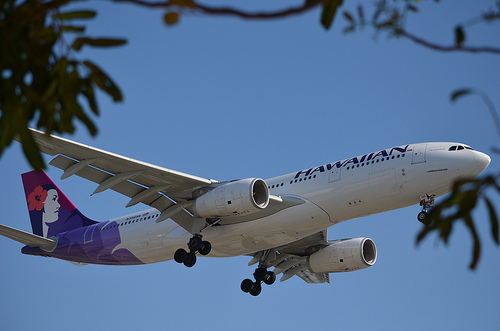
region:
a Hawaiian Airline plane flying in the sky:
[1, 116, 492, 298]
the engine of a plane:
[185, 177, 271, 219]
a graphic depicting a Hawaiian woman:
[15, 166, 142, 272]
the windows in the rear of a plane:
[106, 212, 158, 227]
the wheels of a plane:
[171, 232, 275, 298]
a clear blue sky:
[128, 49, 444, 143]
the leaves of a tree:
[6, 6, 118, 118]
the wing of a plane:
[31, 129, 196, 206]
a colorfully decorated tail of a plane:
[16, 168, 92, 228]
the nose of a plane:
[466, 147, 491, 168]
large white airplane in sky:
[25, 81, 482, 298]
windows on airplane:
[266, 168, 324, 195]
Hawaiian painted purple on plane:
[289, 133, 414, 192]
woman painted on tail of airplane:
[25, 162, 80, 239]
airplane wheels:
[166, 224, 225, 276]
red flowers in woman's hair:
[25, 182, 57, 220]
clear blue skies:
[176, 63, 331, 130]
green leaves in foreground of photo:
[15, 6, 127, 165]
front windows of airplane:
[447, 133, 480, 160]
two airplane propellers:
[227, 161, 407, 266]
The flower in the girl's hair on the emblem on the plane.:
[23, 184, 52, 214]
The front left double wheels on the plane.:
[191, 235, 211, 253]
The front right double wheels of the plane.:
[255, 260, 273, 282]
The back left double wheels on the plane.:
[171, 245, 200, 268]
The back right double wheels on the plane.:
[241, 276, 262, 293]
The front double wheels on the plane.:
[416, 189, 446, 203]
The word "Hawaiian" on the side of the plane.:
[293, 146, 409, 183]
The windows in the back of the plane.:
[91, 213, 161, 233]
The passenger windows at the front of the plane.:
[342, 151, 405, 175]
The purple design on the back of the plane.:
[58, 230, 142, 267]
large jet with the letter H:
[293, 160, 315, 191]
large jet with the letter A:
[310, 156, 327, 188]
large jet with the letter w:
[324, 153, 352, 176]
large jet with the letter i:
[355, 145, 375, 173]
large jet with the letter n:
[384, 140, 419, 164]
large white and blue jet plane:
[0, 118, 490, 280]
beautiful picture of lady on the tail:
[2, 148, 132, 251]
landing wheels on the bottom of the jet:
[125, 215, 312, 299]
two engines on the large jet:
[180, 147, 405, 279]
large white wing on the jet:
[12, 100, 292, 250]